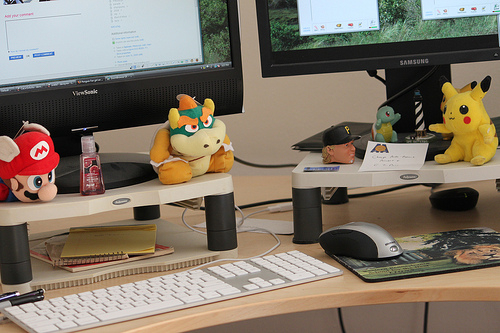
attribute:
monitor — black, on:
[252, 0, 500, 82]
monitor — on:
[1, 1, 248, 130]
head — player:
[323, 124, 360, 165]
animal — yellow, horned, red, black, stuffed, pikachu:
[425, 75, 500, 167]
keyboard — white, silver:
[2, 247, 347, 332]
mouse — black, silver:
[317, 217, 404, 263]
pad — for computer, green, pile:
[320, 225, 500, 284]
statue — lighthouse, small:
[405, 88, 434, 140]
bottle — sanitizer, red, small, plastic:
[75, 134, 107, 198]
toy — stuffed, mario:
[2, 120, 62, 208]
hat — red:
[1, 128, 62, 182]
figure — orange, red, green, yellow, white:
[149, 94, 236, 189]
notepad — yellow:
[57, 224, 159, 263]